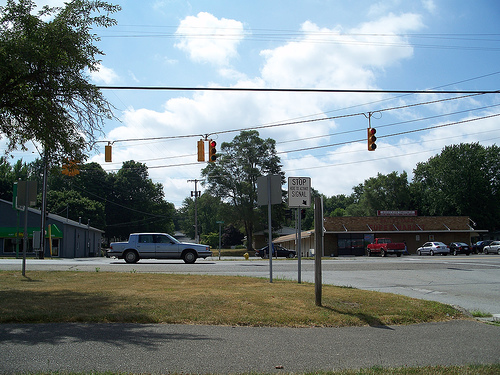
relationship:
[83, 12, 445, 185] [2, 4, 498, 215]
clouds in sky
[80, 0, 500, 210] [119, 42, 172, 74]
clouds in sky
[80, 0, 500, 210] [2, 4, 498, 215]
clouds in sky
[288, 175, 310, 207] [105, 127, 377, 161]
sign in signal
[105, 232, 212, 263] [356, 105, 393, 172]
car waiting at stoplight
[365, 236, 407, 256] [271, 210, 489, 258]
truck parked at building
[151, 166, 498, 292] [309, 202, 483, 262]
cars at a business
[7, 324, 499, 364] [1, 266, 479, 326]
walkway middle of grass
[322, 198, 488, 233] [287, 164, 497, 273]
roof of a building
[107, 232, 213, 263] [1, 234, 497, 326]
car on road